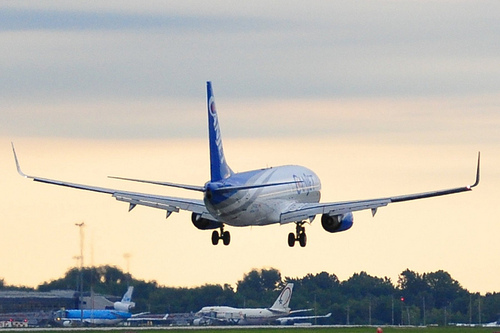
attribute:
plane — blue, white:
[48, 280, 178, 331]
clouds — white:
[3, 7, 497, 271]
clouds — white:
[365, 29, 381, 75]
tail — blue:
[203, 79, 229, 181]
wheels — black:
[208, 229, 310, 249]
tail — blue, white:
[199, 79, 239, 189]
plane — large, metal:
[10, 80, 482, 245]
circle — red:
[279, 286, 291, 308]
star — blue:
[276, 297, 283, 304]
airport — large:
[4, 286, 78, 313]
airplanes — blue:
[192, 282, 335, 325]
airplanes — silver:
[53, 290, 164, 326]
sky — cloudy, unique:
[206, 25, 483, 127]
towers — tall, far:
[71, 217, 133, 275]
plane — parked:
[49, 286, 170, 326]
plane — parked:
[192, 281, 334, 325]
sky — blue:
[5, 3, 498, 287]